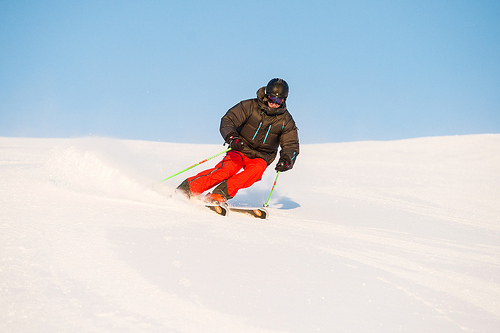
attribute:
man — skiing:
[175, 77, 302, 206]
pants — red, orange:
[176, 150, 270, 200]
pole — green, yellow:
[155, 147, 235, 184]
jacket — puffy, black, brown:
[218, 86, 301, 167]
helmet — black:
[264, 78, 290, 105]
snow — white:
[1, 138, 499, 332]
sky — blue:
[1, 1, 497, 143]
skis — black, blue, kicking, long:
[202, 204, 268, 222]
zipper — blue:
[262, 123, 274, 147]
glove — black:
[230, 135, 246, 153]